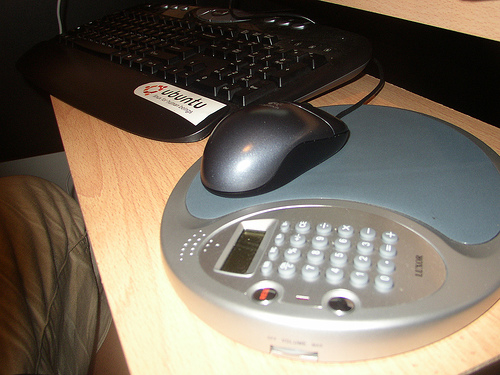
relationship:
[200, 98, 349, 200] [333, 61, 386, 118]
mouse with cable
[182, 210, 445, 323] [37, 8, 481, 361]
calculator on table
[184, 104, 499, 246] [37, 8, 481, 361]
mouse pad on table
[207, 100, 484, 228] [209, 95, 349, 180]
mouse pad with mouse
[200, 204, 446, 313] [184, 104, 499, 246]
calculator attached to mouse pad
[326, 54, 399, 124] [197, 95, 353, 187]
cable to computer mouse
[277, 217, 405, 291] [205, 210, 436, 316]
keypad on calculator